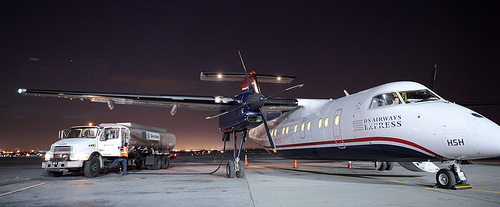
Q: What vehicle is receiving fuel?
A: The plane.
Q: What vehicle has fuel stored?
A: The tanker.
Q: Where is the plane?
A: On the tarmac.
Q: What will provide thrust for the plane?
A: The propellers.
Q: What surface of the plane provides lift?
A: The wing.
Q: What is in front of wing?
A: Propeller.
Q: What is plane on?
A: Ground.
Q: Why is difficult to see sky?
A: Dark.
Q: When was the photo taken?
A: At night.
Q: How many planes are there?
A: One.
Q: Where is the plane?
A: On the runway.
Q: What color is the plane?
A: White.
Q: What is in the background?
A: Buildings.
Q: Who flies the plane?
A: A pilot.